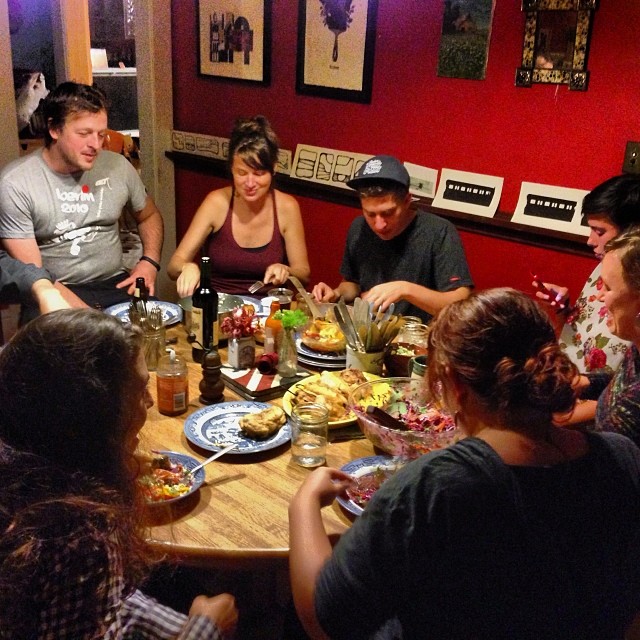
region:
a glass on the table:
[290, 406, 337, 469]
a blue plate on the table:
[196, 403, 282, 450]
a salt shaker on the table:
[201, 349, 223, 401]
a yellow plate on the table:
[290, 366, 375, 412]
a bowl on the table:
[352, 378, 453, 444]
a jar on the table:
[155, 359, 184, 405]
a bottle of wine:
[189, 256, 216, 345]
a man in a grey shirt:
[348, 187, 454, 299]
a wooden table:
[37, 308, 570, 568]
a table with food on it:
[54, 296, 573, 564]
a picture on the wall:
[300, 7, 372, 95]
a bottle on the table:
[156, 356, 188, 402]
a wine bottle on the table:
[197, 257, 218, 353]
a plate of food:
[128, 448, 203, 505]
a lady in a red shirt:
[192, 185, 317, 284]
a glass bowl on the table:
[356, 380, 437, 447]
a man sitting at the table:
[5, 94, 161, 298]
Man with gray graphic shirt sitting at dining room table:
[2, 73, 167, 311]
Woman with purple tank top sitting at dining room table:
[162, 110, 315, 303]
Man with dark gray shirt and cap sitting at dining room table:
[309, 143, 479, 325]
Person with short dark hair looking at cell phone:
[519, 164, 631, 374]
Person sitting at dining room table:
[585, 217, 632, 443]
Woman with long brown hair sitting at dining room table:
[283, 274, 623, 636]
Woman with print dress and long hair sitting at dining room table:
[2, 297, 245, 638]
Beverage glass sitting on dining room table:
[283, 392, 336, 475]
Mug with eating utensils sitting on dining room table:
[325, 289, 407, 381]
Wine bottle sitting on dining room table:
[181, 246, 225, 366]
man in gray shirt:
[3, 82, 164, 305]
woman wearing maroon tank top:
[168, 115, 314, 296]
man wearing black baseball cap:
[309, 156, 474, 315]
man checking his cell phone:
[531, 175, 638, 371]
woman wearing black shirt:
[288, 286, 638, 635]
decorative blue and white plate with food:
[183, 397, 293, 458]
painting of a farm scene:
[434, 0, 494, 80]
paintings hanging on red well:
[171, 0, 638, 320]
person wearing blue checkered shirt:
[3, 309, 237, 639]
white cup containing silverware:
[330, 291, 404, 371]